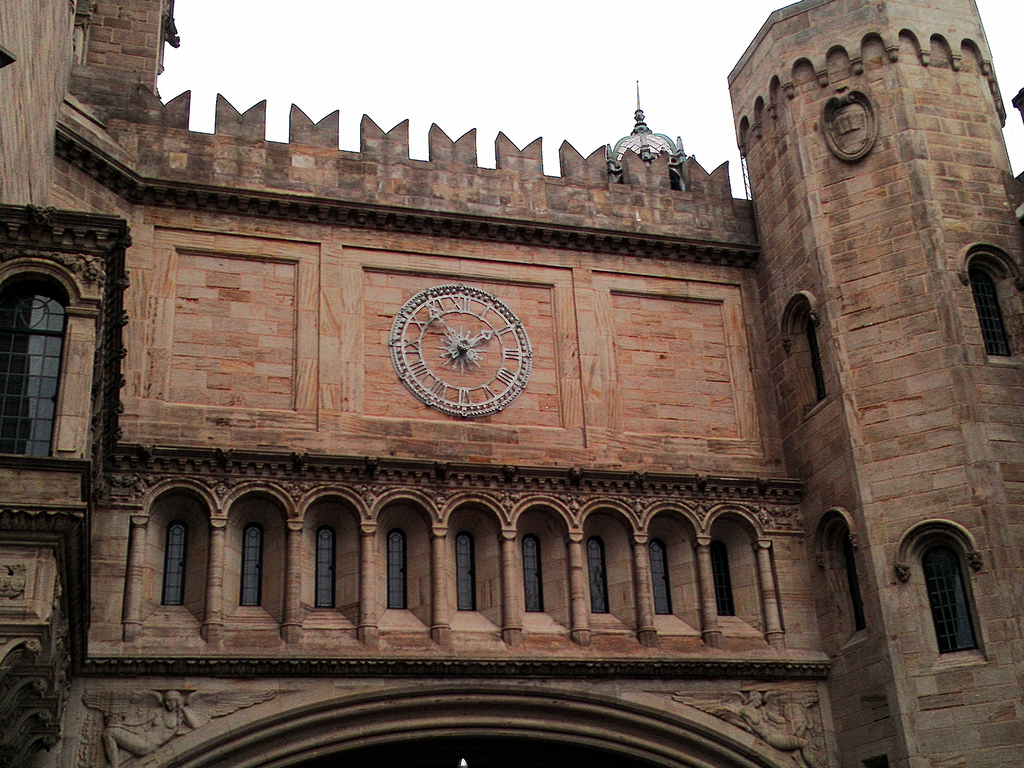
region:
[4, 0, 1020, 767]
Large building constructed with brick masonry.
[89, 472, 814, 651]
Row of narrow windows with arched moldings.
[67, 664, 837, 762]
Decorative carvings above an arched entranceway.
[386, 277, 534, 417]
Large round clock with roman numerals.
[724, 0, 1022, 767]
Tower with a ridged masard top.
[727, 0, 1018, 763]
Tower with inlayed arched windows.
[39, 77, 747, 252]
Ridged brick designs along the roof overlay.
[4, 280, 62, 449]
Window with black glass dividers.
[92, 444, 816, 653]
Pillars inlaid along a row of windows.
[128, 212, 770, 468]
Square brick design behind a large clock.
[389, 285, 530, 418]
a decorative clock fastened to a stone wall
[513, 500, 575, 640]
and arched window in a building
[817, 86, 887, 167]
a crest on a stone wall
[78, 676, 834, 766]
carved angels sitting above an archway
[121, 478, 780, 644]
decorative pillars and arches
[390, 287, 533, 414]
a clock face displaying roman numerals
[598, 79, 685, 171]
a spire on a domed roof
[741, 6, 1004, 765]
a brown stone tower with windows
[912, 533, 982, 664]
a reflection in a window pane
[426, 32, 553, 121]
a cloudy sky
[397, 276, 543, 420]
a clock on the building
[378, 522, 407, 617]
glass window in the castle building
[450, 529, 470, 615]
glass window in the castle building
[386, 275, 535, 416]
a round clock on a building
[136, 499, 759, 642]
a row of windows on a building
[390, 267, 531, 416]
a round metal clock on a building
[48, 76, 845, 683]
this is a castle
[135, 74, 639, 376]
the castle is ornate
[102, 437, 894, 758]
this is an archway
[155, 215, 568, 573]
the bricks are tan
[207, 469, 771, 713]
the windows are rowed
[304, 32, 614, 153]
the sky is overcast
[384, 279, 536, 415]
a black metal clock face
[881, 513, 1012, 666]
a black inset window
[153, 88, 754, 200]
a line of carved stone points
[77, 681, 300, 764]
a stone relief angel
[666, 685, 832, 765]
a stone relief angel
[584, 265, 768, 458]
an inset brick square design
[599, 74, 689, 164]
a pointed black spire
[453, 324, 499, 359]
a metal hour hand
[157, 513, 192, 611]
A window on a building.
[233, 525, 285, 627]
A window on a building.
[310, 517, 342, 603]
A window on a building.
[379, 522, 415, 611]
A window on a building.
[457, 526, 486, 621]
A window on a building.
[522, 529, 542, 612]
A window on a building.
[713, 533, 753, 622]
A window on a building.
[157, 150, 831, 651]
the building is brick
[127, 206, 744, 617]
the bricks are tan